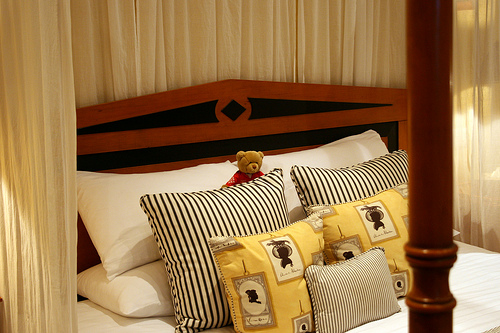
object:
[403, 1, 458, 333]
post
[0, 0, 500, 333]
curtain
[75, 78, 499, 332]
bed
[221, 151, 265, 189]
teddy bear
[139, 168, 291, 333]
stripes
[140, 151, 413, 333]
pillow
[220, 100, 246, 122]
square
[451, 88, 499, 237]
light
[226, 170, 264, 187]
shirt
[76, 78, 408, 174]
headboard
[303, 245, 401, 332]
pillow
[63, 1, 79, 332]
edge